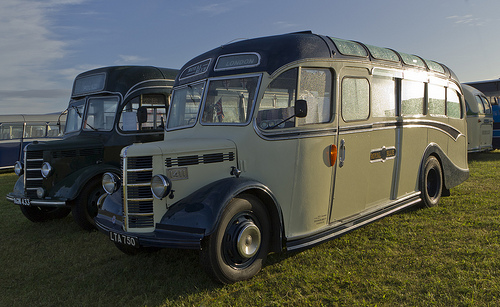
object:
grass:
[0, 148, 497, 306]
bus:
[460, 84, 493, 153]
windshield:
[64, 96, 120, 135]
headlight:
[102, 172, 121, 195]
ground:
[366, 243, 428, 269]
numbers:
[122, 235, 135, 246]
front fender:
[6, 194, 68, 207]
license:
[110, 232, 136, 246]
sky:
[0, 0, 498, 67]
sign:
[71, 72, 107, 98]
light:
[331, 142, 337, 166]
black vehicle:
[6, 65, 330, 232]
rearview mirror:
[294, 99, 307, 118]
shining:
[372, 60, 448, 129]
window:
[165, 72, 263, 131]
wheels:
[199, 195, 270, 286]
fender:
[198, 177, 283, 253]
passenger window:
[297, 67, 464, 126]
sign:
[179, 52, 262, 81]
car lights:
[151, 174, 172, 199]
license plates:
[14, 198, 30, 205]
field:
[300, 235, 498, 294]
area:
[3, 117, 59, 141]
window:
[118, 93, 166, 131]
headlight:
[41, 162, 53, 178]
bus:
[93, 30, 469, 285]